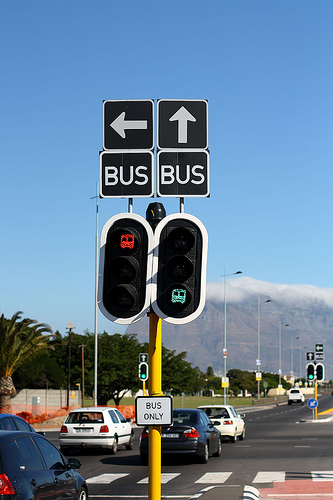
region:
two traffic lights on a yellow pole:
[88, 200, 214, 494]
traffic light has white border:
[96, 206, 154, 327]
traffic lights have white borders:
[301, 360, 326, 420]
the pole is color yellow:
[139, 312, 168, 498]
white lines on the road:
[82, 467, 332, 489]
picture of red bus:
[109, 229, 142, 248]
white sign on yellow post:
[122, 389, 187, 425]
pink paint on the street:
[275, 477, 306, 496]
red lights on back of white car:
[57, 421, 116, 443]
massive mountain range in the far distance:
[228, 265, 302, 362]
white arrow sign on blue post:
[302, 397, 318, 408]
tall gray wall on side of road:
[32, 378, 86, 426]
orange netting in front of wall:
[25, 392, 62, 421]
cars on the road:
[44, 405, 252, 462]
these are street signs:
[74, 91, 232, 336]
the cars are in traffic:
[81, 361, 211, 454]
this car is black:
[136, 424, 221, 453]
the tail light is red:
[164, 422, 207, 438]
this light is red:
[94, 236, 152, 337]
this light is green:
[146, 229, 222, 347]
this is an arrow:
[110, 71, 178, 156]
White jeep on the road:
[284, 380, 305, 408]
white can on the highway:
[196, 390, 242, 433]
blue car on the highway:
[139, 400, 224, 455]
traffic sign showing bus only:
[132, 391, 172, 425]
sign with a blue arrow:
[308, 397, 318, 409]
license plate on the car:
[74, 426, 93, 433]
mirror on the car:
[63, 456, 86, 472]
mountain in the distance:
[223, 276, 332, 365]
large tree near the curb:
[59, 333, 147, 398]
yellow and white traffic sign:
[213, 372, 233, 389]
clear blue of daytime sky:
[0, 0, 331, 335]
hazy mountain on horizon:
[122, 274, 331, 385]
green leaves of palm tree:
[0, 310, 55, 412]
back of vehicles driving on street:
[1, 386, 331, 498]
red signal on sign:
[101, 207, 153, 259]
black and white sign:
[118, 387, 182, 443]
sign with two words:
[115, 385, 184, 440]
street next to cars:
[244, 427, 308, 470]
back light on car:
[172, 413, 211, 453]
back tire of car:
[101, 433, 130, 461]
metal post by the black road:
[145, 312, 161, 498]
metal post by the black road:
[94, 181, 99, 407]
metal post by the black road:
[221, 263, 227, 404]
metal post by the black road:
[255, 294, 259, 401]